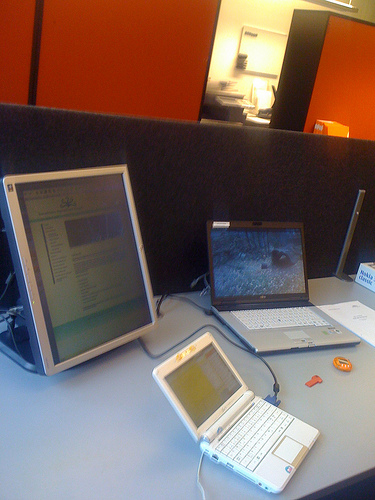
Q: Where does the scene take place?
A: In an office.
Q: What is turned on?
A: Computer screens.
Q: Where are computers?
A: On the desk.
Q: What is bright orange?
A: The wall.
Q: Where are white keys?
A: On laptop's keyboard.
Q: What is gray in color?
A: The desk.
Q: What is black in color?
A: An electrical cord.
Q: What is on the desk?
A: Some computers.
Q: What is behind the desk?
A: An open door.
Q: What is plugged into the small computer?
A: A cable.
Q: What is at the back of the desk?
A: A black panel.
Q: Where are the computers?
A: On a desk.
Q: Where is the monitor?
A: On a desk.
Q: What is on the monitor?
A: A web page.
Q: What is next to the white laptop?
A: Two orange devices.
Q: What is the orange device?
A: A digital game.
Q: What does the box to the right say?
A: Nokia classic.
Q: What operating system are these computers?
A: Windows.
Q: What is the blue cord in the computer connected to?
A: A monitor.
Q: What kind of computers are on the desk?
A: Laptops.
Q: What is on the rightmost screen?
A: An image.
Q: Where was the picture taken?
A: An office.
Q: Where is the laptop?
A: On the desk on the right.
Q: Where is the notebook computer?
A: Bottom of photo.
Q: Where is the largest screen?
A: On the left.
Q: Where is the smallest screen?
A: Bottom of scene.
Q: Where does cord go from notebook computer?
A: To the back of the desk.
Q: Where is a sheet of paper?
A: Right of the laptop.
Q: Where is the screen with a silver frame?
A: Upper left.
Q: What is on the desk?
A: Computers.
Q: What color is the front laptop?
A: White.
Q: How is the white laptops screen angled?
A: It is slightly pushed back.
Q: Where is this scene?
A: An office.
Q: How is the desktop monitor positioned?
A: On its side.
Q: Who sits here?
A: An office worker.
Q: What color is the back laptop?
A: Silver.